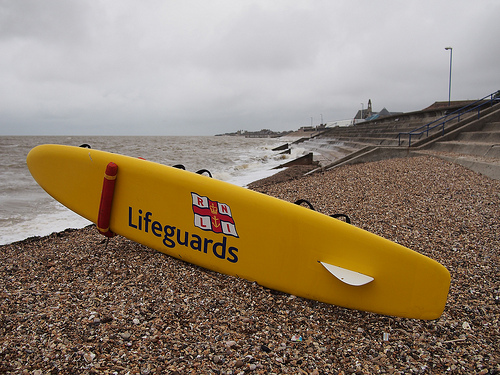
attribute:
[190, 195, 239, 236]
flag — decorative 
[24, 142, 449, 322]
surf board — yellow 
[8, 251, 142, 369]
beach — rocky 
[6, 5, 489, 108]
cloudy day — overcast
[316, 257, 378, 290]
fin on surf board — yellow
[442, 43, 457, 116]
light pole on stairs — cement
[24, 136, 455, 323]
lifeguard surfboard — yellow, red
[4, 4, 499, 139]
white clouds in sky — grey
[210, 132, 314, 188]
white waves in ocean — brown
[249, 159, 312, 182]
wave crash to shore — white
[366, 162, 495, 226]
stones on the sand — brown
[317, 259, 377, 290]
white fin on board — yellow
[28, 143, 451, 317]
large surf board — yellow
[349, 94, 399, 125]
house at a distance — large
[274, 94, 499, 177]
houses are visible — distant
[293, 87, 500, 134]
houses are visible — distant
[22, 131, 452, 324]
board is visible — yellow